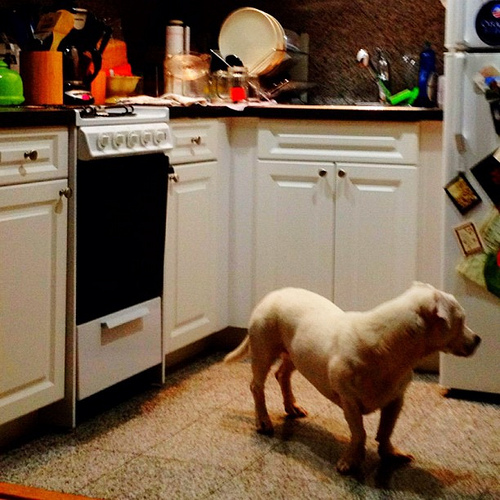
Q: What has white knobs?
A: Oven.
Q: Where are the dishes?
A: Drying rack.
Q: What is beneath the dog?
A: Shadow.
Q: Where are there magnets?
A: On refrigerator.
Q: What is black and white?
A: The stove is black and white.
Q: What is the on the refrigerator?
A: They are Magnets on the refrigerator.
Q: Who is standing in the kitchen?
A: A light brown dog is standing in the kitchen.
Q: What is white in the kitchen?
A: A white refridgerator/freezer unit is in the kitchen.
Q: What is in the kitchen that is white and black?
A: A white and black oven/stove is in the kitchen.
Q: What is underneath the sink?
A: A white cabinet is underneath the sink.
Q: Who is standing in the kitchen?
A: A white dog is standing in the kitchen.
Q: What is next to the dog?
A: A white oven is next to the dog.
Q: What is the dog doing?
A: Standing in the kitchen.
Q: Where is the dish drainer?
A: By the sink.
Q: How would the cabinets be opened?
A: By the knobs.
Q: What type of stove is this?
A: Gas.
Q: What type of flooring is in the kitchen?
A: Tile.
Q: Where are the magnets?
A: On the refrigerator.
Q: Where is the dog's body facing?
A: Right.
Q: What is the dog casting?
A: Its shadow.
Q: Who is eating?
A: No one.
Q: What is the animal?
A: Dog.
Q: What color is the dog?
A: Tan.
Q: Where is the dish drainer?
A: Left of sink.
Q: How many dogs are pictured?
A: One.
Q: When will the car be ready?
A: No car.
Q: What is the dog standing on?
A: The floor.